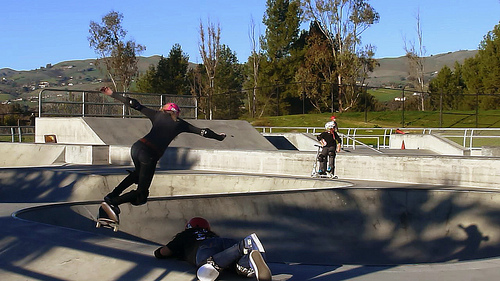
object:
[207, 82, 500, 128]
fence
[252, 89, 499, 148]
grass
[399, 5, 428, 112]
tree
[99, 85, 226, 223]
girl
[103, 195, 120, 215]
sneaker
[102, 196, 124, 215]
foot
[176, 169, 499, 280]
shadows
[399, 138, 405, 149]
cone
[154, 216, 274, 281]
person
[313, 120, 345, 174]
child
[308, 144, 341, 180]
scooter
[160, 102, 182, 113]
helmet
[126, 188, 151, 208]
knee pad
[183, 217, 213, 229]
helmet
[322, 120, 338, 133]
helmet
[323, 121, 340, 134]
head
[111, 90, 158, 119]
arm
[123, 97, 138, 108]
elbow pad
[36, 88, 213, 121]
rail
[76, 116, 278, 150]
ramp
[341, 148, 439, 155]
ramp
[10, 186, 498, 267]
ramp